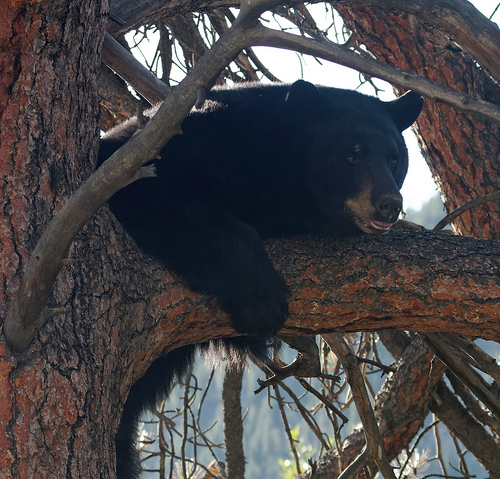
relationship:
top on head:
[323, 87, 397, 134] [271, 72, 429, 239]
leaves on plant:
[279, 420, 307, 463] [274, 414, 334, 477]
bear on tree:
[98, 79, 423, 338] [8, 5, 498, 425]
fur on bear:
[216, 128, 245, 146] [78, 66, 433, 356]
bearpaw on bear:
[208, 270, 295, 333] [92, 79, 423, 479]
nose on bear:
[371, 190, 403, 222] [92, 79, 423, 479]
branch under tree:
[300, 336, 449, 479] [81, 207, 473, 319]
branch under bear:
[113, 217, 500, 376] [122, 73, 429, 308]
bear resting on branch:
[92, 79, 423, 479] [101, 199, 498, 407]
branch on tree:
[101, 199, 498, 407] [1, 1, 496, 477]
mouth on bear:
[349, 187, 399, 234] [92, 79, 423, 479]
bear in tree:
[92, 79, 423, 479] [356, 5, 487, 105]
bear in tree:
[98, 79, 423, 338] [1, 1, 496, 477]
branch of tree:
[319, 332, 401, 477] [1, 1, 496, 477]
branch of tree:
[300, 336, 449, 479] [1, 1, 496, 477]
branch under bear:
[113, 217, 500, 376] [97, 70, 444, 331]